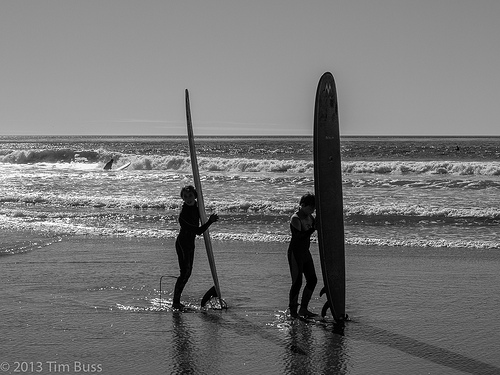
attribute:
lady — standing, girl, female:
[286, 193, 320, 319]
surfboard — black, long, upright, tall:
[314, 70, 347, 324]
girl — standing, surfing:
[172, 185, 199, 310]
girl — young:
[173, 187, 218, 308]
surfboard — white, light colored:
[185, 87, 226, 311]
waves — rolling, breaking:
[2, 143, 184, 175]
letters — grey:
[13, 360, 103, 374]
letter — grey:
[74, 358, 83, 372]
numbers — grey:
[3, 360, 44, 374]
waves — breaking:
[347, 140, 499, 252]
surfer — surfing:
[103, 158, 131, 175]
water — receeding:
[1, 265, 499, 374]